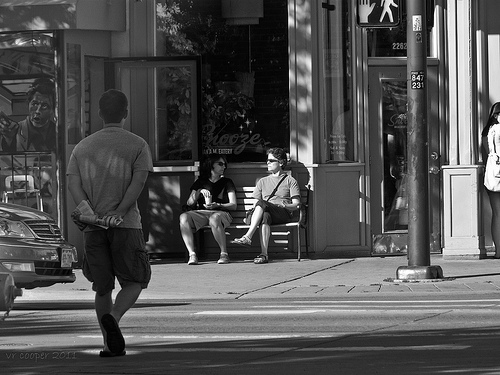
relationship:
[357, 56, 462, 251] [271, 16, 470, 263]
door in building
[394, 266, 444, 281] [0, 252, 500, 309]
post in sidewalk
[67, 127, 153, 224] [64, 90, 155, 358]
shirt in man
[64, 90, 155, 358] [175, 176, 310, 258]
man in bench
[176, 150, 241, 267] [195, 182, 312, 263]
woman in bench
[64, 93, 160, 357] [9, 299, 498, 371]
man in street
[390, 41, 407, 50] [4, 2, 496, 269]
address in building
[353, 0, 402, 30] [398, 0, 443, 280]
sign on pole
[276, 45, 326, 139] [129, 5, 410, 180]
sunlight on building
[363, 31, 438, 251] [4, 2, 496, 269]
door of a building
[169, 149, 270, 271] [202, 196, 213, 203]
woman holding beverage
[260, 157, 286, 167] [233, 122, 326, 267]
sunglasses on woman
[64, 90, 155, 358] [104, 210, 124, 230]
man has hand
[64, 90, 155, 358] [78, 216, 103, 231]
man has hand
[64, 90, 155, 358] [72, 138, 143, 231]
man has back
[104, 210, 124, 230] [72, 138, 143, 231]
hand behind back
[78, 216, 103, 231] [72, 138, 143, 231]
hand behind back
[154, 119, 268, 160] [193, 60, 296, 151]
name on window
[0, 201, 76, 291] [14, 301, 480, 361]
car on street